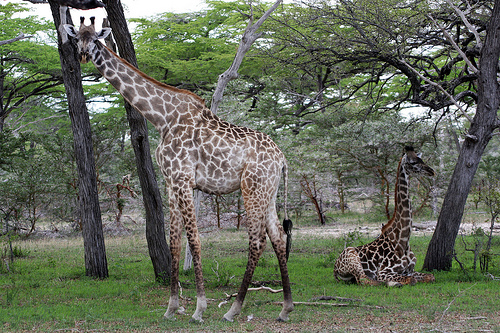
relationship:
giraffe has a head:
[63, 16, 294, 324] [62, 16, 110, 65]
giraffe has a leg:
[63, 16, 294, 324] [221, 167, 279, 322]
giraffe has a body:
[63, 16, 294, 324] [155, 116, 286, 194]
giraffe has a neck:
[63, 16, 294, 324] [95, 51, 189, 129]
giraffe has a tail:
[63, 16, 294, 324] [282, 169, 291, 236]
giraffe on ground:
[63, 16, 294, 324] [2, 224, 499, 333]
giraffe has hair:
[63, 16, 294, 324] [79, 27, 96, 37]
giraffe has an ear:
[63, 16, 294, 324] [99, 23, 112, 42]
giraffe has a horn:
[63, 16, 294, 324] [90, 18, 95, 27]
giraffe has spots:
[63, 16, 294, 324] [218, 139, 229, 151]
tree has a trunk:
[48, 2, 110, 277] [423, 124, 498, 270]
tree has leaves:
[48, 2, 110, 277] [0, 3, 499, 112]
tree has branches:
[48, 2, 110, 277] [228, 5, 496, 126]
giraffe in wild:
[63, 16, 294, 324] [1, 2, 498, 332]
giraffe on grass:
[63, 16, 294, 324] [2, 225, 499, 333]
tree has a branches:
[48, 2, 110, 277] [228, 5, 496, 126]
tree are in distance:
[48, 2, 110, 277] [2, 2, 497, 276]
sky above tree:
[2, 2, 496, 122] [48, 2, 110, 277]